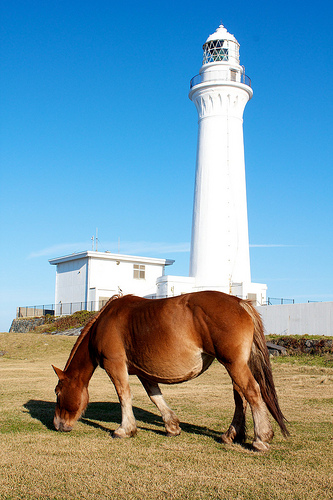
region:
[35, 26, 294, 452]
a horse grazing in front of a lighthouse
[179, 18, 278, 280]
a tall white lighthouse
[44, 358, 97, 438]
the head of a horse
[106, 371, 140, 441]
the leg of a horse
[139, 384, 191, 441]
the leg of a horse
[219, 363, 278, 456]
the rear legs of a horse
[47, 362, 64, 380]
the ear of a horse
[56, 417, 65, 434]
the mouth of a horse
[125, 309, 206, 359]
the fur of a horse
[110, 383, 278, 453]
the legs of a horse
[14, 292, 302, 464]
red horse grazing on grass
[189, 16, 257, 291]
a tall, white lighthouse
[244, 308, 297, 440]
long brown tail of horse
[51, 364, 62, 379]
brown left ear of horse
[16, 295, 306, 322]
metal fence around buildings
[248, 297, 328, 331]
a large, smooth gray wall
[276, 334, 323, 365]
dark green vegetation around rocks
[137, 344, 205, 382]
belly of a horse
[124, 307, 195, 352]
brown fur on the side of a horse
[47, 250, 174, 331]
large white building on top of hill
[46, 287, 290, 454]
a horse eating some grass.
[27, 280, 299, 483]
this horse looks pregnant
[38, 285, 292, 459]
she is a small horse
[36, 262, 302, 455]
she is a bay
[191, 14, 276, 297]
a bright white light house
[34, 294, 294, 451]
the horse is grazing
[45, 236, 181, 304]
the building next to the lighthouse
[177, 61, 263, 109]
the widows walk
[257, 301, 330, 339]
a fence encloses the areas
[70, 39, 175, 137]
the sky is so perfectly blue & brilliant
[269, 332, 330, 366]
rocks are in the background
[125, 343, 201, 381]
fat stomach of horse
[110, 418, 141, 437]
front left hoof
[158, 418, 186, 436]
front right hoof of horse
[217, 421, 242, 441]
back right hoof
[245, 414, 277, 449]
back left hoof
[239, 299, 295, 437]
long horse's tail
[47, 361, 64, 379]
left ear of the horse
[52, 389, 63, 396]
left eye of the horse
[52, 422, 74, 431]
mouth of the brown horse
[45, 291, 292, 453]
beautiful brown horse eating grass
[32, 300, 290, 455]
horse eating green grass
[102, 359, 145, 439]
leg of a horse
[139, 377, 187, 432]
leg of a horse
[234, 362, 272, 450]
leg of a horse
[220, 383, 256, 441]
leg of a horse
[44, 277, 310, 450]
brown horse grazing grass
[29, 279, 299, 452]
brown horse grazing grass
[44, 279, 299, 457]
brown horse grazing grass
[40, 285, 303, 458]
brown horse grazing grass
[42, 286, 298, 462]
brown horse grazing grass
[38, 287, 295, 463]
brown horse grazing grass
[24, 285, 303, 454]
brown horse grazing grass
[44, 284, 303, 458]
brown horse grazing grass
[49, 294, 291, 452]
large brown hairy horse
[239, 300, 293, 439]
long brown horse tail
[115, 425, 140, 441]
large round horse hoof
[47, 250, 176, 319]
large white square building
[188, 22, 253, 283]
tall white large lighthouse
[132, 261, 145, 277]
small square glass window